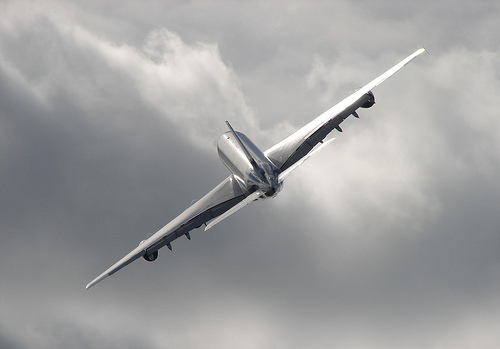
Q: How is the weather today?
A: It is overcast.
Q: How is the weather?
A: It is overcast.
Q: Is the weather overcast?
A: Yes, it is overcast.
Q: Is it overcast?
A: Yes, it is overcast.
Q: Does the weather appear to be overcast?
A: Yes, it is overcast.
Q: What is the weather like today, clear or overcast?
A: It is overcast.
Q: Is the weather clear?
A: No, it is overcast.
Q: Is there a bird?
A: No, there are no birds.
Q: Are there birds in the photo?
A: No, there are no birds.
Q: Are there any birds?
A: No, there are no birds.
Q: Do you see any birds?
A: No, there are no birds.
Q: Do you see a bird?
A: No, there are no birds.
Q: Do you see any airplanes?
A: Yes, there is an airplane.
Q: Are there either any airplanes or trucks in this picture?
A: Yes, there is an airplane.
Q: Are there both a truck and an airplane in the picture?
A: No, there is an airplane but no trucks.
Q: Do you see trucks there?
A: No, there are no trucks.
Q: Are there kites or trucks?
A: No, there are no trucks or kites.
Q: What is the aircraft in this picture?
A: The aircraft is an airplane.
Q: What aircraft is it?
A: The aircraft is an airplane.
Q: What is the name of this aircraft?
A: That is an airplane.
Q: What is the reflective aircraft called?
A: The aircraft is an airplane.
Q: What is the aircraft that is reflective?
A: The aircraft is an airplane.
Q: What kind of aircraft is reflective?
A: The aircraft is an airplane.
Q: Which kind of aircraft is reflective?
A: The aircraft is an airplane.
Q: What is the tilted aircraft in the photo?
A: The aircraft is an airplane.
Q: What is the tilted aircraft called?
A: The aircraft is an airplane.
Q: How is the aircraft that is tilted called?
A: The aircraft is an airplane.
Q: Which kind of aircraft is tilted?
A: The aircraft is an airplane.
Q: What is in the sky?
A: The airplane is in the sky.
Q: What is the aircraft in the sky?
A: The aircraft is an airplane.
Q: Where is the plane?
A: The plane is in the sky.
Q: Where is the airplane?
A: The plane is in the sky.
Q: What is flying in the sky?
A: The plane is flying in the sky.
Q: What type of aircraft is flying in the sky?
A: The aircraft is an airplane.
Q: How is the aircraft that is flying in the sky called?
A: The aircraft is an airplane.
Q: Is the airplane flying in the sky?
A: Yes, the airplane is flying in the sky.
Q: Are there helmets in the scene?
A: No, there are no helmets.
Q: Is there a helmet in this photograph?
A: No, there are no helmets.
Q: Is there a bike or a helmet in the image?
A: No, there are no helmets or bikes.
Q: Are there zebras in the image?
A: No, there are no zebras.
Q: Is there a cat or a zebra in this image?
A: No, there are no zebras or cats.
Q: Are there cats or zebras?
A: No, there are no zebras or cats.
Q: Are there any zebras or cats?
A: No, there are no zebras or cats.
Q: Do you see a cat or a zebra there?
A: No, there are no zebras or cats.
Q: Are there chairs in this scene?
A: No, there are no chairs.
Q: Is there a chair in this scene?
A: No, there are no chairs.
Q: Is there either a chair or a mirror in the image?
A: No, there are no chairs or mirrors.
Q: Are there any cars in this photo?
A: No, there are no cars.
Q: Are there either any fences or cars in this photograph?
A: No, there are no cars or fences.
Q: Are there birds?
A: No, there are no birds.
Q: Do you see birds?
A: No, there are no birds.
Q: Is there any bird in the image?
A: No, there are no birds.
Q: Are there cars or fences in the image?
A: No, there are no cars or fences.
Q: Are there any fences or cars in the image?
A: No, there are no cars or fences.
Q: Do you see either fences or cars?
A: No, there are no cars or fences.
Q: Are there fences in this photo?
A: No, there are no fences.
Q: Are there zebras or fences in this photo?
A: No, there are no fences or zebras.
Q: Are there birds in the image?
A: No, there are no birds.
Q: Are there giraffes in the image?
A: No, there are no giraffes.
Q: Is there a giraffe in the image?
A: No, there are no giraffes.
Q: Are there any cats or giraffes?
A: No, there are no giraffes or cats.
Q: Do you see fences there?
A: No, there are no fences.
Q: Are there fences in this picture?
A: No, there are no fences.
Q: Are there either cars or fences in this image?
A: No, there are no fences or cars.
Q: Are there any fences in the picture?
A: No, there are no fences.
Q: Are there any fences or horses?
A: No, there are no fences or horses.